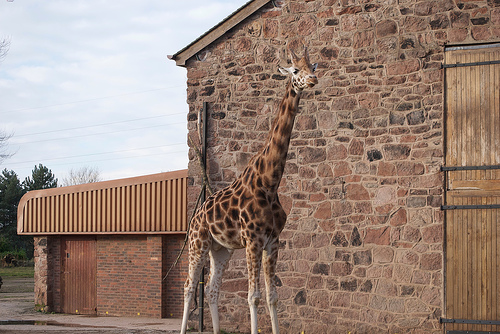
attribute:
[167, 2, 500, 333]
stone — multicolored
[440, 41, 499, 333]
door — wooden, brown, tall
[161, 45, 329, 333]
giraffe — tall, brown, white, standing, patterned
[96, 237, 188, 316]
bricks — brown, red, black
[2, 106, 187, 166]
electrical lines — black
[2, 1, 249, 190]
sky — blue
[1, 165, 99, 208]
trees — green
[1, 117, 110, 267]
trees — green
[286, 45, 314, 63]
horns — small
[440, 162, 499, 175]
latch — black, metal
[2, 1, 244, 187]
clouds — white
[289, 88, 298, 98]
spot — brown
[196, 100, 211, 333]
pole — black, metal, leaning, long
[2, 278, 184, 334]
ground — concrete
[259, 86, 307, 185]
neck — long